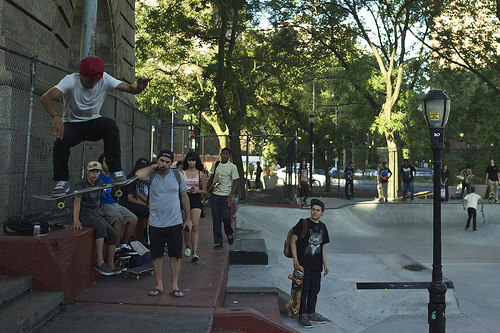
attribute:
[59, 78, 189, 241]
teeshirt — gray, white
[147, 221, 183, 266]
shorts — black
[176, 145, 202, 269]
girl — walking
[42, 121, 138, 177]
pants — black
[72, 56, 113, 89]
cap — red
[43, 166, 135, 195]
sneakers — gray